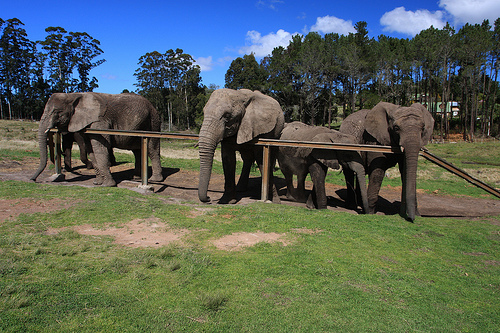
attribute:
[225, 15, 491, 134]
tree line — green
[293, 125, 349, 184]
elephant — herd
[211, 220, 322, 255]
dirt patch — couple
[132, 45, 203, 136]
tree — green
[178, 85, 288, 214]
elephant — large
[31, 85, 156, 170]
elephant —   Juvenile,   African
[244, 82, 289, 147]
ear — large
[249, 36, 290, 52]
clouds — some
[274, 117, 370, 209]
baby elephant — baby 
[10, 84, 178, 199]
elephant — large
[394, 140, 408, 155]
elephant tusk — small and white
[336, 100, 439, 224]
animal — some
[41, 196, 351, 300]
patches — some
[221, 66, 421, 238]
elephants — gray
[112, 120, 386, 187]
rail — brown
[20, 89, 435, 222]
elephants — large,  four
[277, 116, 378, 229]
elephant — small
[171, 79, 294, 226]
elephant — large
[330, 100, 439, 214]
elephant — large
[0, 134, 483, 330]
grass — some, green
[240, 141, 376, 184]
rail — rusty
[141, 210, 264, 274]
dirt — patches